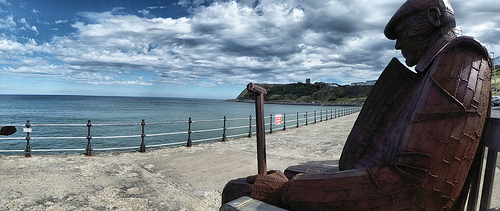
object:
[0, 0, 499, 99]
sky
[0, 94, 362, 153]
water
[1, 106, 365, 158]
railing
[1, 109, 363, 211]
walkway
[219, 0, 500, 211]
statue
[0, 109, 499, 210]
bench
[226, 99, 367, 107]
jetty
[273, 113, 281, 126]
sign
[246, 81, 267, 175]
cane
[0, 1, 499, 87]
clouds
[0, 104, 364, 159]
gate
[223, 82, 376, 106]
rocks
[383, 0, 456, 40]
hat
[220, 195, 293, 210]
armrest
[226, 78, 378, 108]
cliff